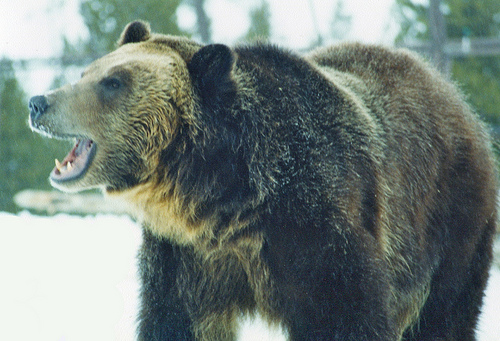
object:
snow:
[64, 205, 113, 319]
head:
[24, 18, 242, 195]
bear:
[23, 18, 499, 340]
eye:
[102, 75, 119, 89]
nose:
[24, 92, 50, 119]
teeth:
[54, 158, 70, 174]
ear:
[188, 42, 237, 102]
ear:
[114, 18, 152, 47]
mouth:
[28, 118, 104, 187]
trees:
[55, 2, 215, 201]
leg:
[277, 289, 416, 340]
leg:
[135, 231, 235, 341]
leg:
[406, 220, 494, 339]